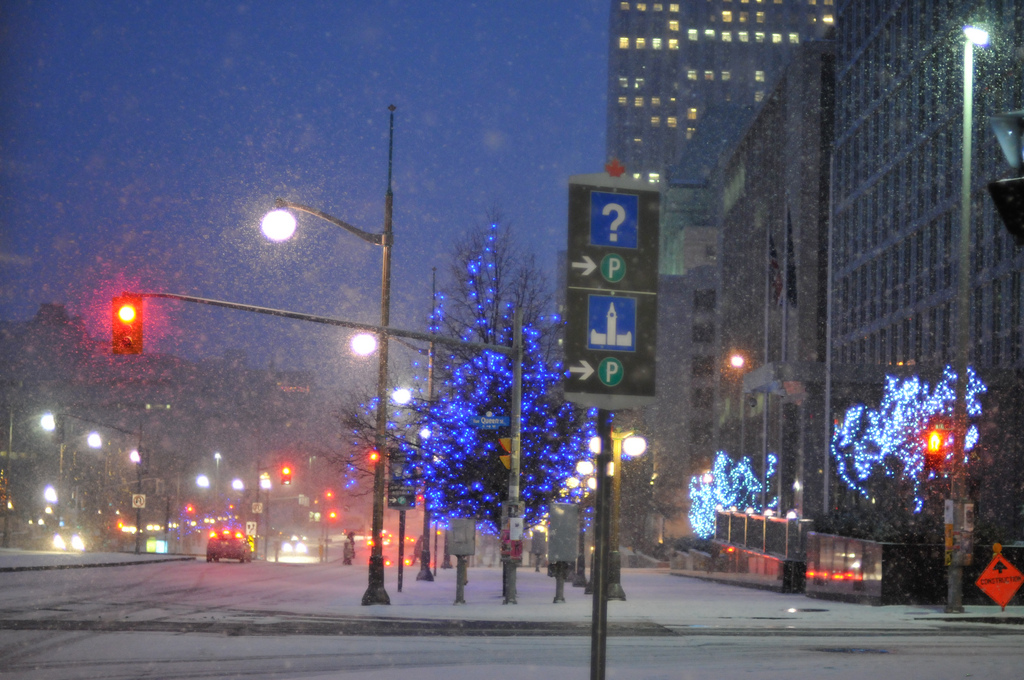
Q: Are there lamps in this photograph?
A: Yes, there is a lamp.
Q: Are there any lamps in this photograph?
A: Yes, there is a lamp.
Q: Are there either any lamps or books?
A: Yes, there is a lamp.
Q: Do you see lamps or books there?
A: Yes, there is a lamp.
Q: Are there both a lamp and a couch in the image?
A: No, there is a lamp but no couches.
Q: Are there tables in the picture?
A: No, there are no tables.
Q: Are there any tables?
A: No, there are no tables.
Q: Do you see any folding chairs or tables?
A: No, there are no tables or folding chairs.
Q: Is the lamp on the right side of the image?
A: Yes, the lamp is on the right of the image.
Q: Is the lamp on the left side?
A: No, the lamp is on the right of the image.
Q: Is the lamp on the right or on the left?
A: The lamp is on the right of the image.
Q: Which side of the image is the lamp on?
A: The lamp is on the right of the image.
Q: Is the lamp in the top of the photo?
A: Yes, the lamp is in the top of the image.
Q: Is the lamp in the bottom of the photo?
A: No, the lamp is in the top of the image.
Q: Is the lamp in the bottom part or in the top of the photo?
A: The lamp is in the top of the image.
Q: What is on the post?
A: The lamp is on the post.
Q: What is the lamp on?
A: The lamp is on the post.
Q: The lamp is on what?
A: The lamp is on the post.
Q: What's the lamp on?
A: The lamp is on the post.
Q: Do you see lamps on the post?
A: Yes, there is a lamp on the post.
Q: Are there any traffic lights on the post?
A: No, there is a lamp on the post.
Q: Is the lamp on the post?
A: Yes, the lamp is on the post.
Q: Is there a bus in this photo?
A: No, there are no buses.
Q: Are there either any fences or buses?
A: No, there are no buses or fences.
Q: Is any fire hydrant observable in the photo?
A: No, there are no fire hydrants.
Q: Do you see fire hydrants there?
A: No, there are no fire hydrants.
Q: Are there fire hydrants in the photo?
A: No, there are no fire hydrants.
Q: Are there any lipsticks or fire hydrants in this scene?
A: No, there are no fire hydrants or lipsticks.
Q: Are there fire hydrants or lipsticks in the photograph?
A: No, there are no fire hydrants or lipsticks.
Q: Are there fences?
A: No, there are no fences.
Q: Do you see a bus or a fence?
A: No, there are no fences or buses.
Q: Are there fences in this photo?
A: No, there are no fences.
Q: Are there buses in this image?
A: No, there are no buses.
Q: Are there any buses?
A: No, there are no buses.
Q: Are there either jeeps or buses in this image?
A: No, there are no buses or jeeps.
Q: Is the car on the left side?
A: Yes, the car is on the left of the image.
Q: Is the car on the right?
A: No, the car is on the left of the image.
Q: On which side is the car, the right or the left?
A: The car is on the left of the image.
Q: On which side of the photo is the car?
A: The car is on the left of the image.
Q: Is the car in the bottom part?
A: Yes, the car is in the bottom of the image.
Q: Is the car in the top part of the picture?
A: No, the car is in the bottom of the image.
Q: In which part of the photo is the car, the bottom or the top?
A: The car is in the bottom of the image.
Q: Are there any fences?
A: No, there are no fences.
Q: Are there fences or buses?
A: No, there are no fences or buses.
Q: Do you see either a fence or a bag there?
A: No, there are no fences or bags.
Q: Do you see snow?
A: Yes, there is snow.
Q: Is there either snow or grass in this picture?
A: Yes, there is snow.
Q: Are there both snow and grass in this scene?
A: No, there is snow but no grass.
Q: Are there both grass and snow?
A: No, there is snow but no grass.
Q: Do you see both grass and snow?
A: No, there is snow but no grass.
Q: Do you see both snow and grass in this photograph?
A: No, there is snow but no grass.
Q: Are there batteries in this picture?
A: No, there are no batteries.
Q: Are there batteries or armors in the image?
A: No, there are no batteries or armors.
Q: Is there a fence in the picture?
A: No, there are no fences.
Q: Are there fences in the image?
A: No, there are no fences.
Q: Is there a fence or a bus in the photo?
A: No, there are no fences or buses.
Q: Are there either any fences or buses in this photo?
A: No, there are no fences or buses.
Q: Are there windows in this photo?
A: Yes, there are windows.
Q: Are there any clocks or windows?
A: Yes, there are windows.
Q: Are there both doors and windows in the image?
A: No, there are windows but no doors.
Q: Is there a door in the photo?
A: No, there are no doors.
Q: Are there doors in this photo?
A: No, there are no doors.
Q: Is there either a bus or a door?
A: No, there are no doors or buses.